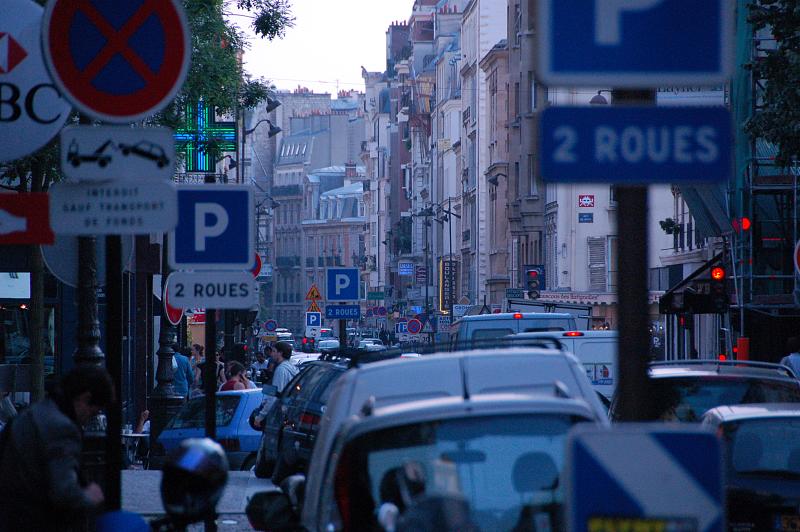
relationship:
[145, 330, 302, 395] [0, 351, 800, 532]
people on busy street